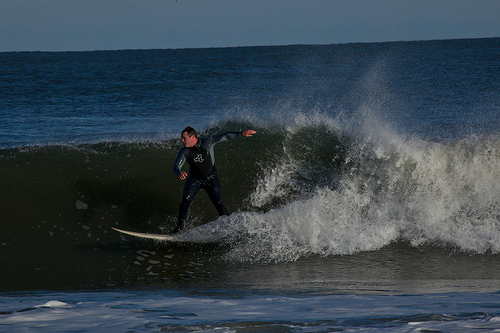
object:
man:
[169, 125, 260, 237]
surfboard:
[109, 226, 182, 242]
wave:
[1, 112, 500, 271]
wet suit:
[172, 132, 244, 226]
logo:
[193, 153, 205, 163]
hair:
[181, 125, 198, 139]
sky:
[2, 0, 499, 54]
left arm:
[208, 129, 257, 147]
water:
[1, 36, 500, 331]